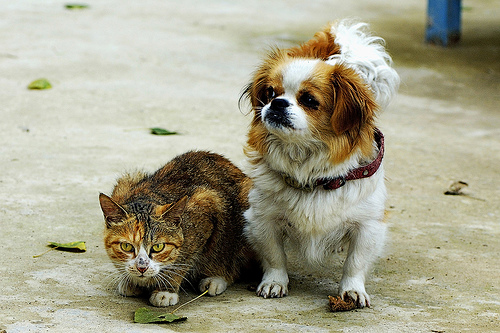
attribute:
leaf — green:
[137, 122, 185, 143]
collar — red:
[274, 121, 387, 192]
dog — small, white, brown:
[252, 47, 394, 307]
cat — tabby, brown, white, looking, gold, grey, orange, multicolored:
[116, 143, 246, 309]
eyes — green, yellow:
[116, 236, 171, 256]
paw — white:
[201, 266, 228, 296]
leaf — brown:
[313, 291, 357, 304]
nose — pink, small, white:
[134, 268, 146, 274]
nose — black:
[267, 94, 292, 124]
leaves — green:
[37, 54, 177, 153]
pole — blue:
[419, 10, 467, 53]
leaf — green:
[134, 310, 201, 328]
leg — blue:
[424, 9, 457, 43]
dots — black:
[136, 256, 149, 262]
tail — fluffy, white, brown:
[331, 20, 412, 100]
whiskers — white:
[106, 259, 190, 299]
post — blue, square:
[416, 1, 467, 49]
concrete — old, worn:
[15, 18, 471, 278]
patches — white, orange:
[299, 67, 365, 142]